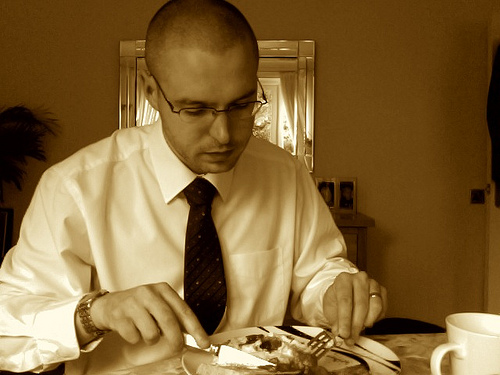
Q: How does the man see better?
A: With the eyeglasses.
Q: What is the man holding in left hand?
A: A fork.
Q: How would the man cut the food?
A: With the knife.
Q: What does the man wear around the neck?
A: A tie.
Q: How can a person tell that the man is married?
A: The wedding ring on his left hand.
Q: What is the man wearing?
A: Glasses.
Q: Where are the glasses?
A: On man's face.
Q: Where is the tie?
A: On the man.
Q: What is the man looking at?
A: Food.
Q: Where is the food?
A: On the plate.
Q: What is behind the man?
A: A window.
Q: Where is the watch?
A: On the man.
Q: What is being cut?
A: The food.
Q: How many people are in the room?
A: One.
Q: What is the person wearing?
A: A tie.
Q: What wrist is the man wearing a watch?
A: Right.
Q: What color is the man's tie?
A: Red.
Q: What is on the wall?
A: A mirror.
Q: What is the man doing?
A: Eating.